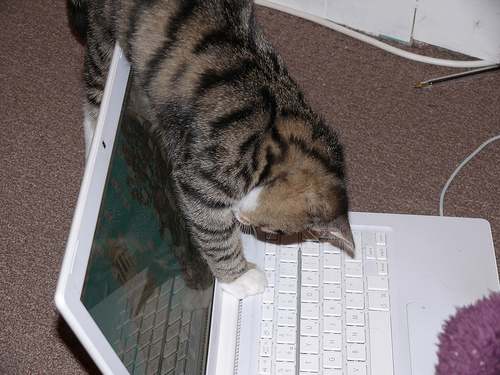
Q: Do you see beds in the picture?
A: No, there are no beds.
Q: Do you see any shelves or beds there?
A: No, there are no beds or shelves.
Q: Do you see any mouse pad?
A: No, there are no mouse pads.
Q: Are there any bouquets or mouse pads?
A: No, there are no mouse pads or bouquets.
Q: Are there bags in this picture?
A: No, there are no bags.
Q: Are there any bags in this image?
A: No, there are no bags.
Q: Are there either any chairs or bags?
A: No, there are no bags or chairs.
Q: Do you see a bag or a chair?
A: No, there are no bags or chairs.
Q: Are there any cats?
A: Yes, there is a cat.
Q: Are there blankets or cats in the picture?
A: Yes, there is a cat.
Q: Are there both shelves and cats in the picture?
A: No, there is a cat but no shelves.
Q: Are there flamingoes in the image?
A: No, there are no flamingoes.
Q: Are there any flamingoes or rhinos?
A: No, there are no flamingoes or rhinos.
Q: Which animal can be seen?
A: The animal is a cat.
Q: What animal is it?
A: The animal is a cat.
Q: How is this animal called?
A: This is a cat.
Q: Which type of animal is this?
A: This is a cat.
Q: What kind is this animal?
A: This is a cat.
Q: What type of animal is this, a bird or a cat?
A: This is a cat.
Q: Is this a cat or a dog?
A: This is a cat.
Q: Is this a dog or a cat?
A: This is a cat.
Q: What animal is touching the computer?
A: The cat is touching the computer.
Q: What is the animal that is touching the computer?
A: The animal is a cat.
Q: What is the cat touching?
A: The cat is touching the computer.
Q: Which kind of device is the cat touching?
A: The cat is touching the computer.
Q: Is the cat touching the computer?
A: Yes, the cat is touching the computer.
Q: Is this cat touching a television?
A: No, the cat is touching the computer.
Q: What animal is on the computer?
A: The cat is on the computer.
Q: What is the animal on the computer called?
A: The animal is a cat.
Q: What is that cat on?
A: The cat is on the computer.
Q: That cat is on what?
A: The cat is on the computer.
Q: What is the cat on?
A: The cat is on the computer.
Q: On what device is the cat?
A: The cat is on the computer.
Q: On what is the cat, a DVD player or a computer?
A: The cat is on a computer.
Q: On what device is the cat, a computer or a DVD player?
A: The cat is on a computer.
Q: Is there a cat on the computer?
A: Yes, there is a cat on the computer.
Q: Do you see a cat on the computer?
A: Yes, there is a cat on the computer.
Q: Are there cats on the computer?
A: Yes, there is a cat on the computer.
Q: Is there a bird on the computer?
A: No, there is a cat on the computer.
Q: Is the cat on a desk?
A: No, the cat is on the computer.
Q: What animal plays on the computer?
A: The cat plays on the computer.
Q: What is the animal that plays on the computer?
A: The animal is a cat.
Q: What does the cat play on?
A: The cat plays on the computer.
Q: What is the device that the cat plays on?
A: The device is a computer.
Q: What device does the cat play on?
A: The cat plays on the computer.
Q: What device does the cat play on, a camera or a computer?
A: The cat plays on a computer.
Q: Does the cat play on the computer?
A: Yes, the cat plays on the computer.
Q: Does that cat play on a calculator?
A: No, the cat plays on the computer.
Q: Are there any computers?
A: Yes, there is a computer.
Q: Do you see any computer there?
A: Yes, there is a computer.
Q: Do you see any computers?
A: Yes, there is a computer.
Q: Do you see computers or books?
A: Yes, there is a computer.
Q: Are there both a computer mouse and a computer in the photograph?
A: No, there is a computer but no computer mice.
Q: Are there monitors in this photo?
A: No, there are no monitors.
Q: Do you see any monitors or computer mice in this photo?
A: No, there are no monitors or computer mice.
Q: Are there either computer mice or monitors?
A: No, there are no monitors or computer mice.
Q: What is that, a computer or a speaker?
A: That is a computer.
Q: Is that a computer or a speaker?
A: That is a computer.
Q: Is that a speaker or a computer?
A: That is a computer.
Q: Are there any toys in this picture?
A: Yes, there is a toy.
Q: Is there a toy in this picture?
A: Yes, there is a toy.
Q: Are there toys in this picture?
A: Yes, there is a toy.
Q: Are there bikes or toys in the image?
A: Yes, there is a toy.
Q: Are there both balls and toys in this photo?
A: No, there is a toy but no balls.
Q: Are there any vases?
A: No, there are no vases.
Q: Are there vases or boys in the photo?
A: No, there are no vases or boys.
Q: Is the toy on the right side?
A: Yes, the toy is on the right of the image.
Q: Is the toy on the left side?
A: No, the toy is on the right of the image.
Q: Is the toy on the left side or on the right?
A: The toy is on the right of the image.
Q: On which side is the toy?
A: The toy is on the right of the image.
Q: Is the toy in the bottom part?
A: Yes, the toy is in the bottom of the image.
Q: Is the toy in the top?
A: No, the toy is in the bottom of the image.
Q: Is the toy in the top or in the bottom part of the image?
A: The toy is in the bottom of the image.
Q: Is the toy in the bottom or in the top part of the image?
A: The toy is in the bottom of the image.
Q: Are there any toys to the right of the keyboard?
A: Yes, there is a toy to the right of the keyboard.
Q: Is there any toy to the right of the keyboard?
A: Yes, there is a toy to the right of the keyboard.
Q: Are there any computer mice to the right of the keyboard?
A: No, there is a toy to the right of the keyboard.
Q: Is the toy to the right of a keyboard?
A: Yes, the toy is to the right of a keyboard.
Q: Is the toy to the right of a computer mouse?
A: No, the toy is to the right of a keyboard.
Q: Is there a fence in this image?
A: No, there are no fences.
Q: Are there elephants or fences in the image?
A: No, there are no fences or elephants.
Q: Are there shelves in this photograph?
A: No, there are no shelves.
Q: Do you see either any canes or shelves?
A: No, there are no shelves or canes.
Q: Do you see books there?
A: No, there are no books.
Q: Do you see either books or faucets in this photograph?
A: No, there are no books or faucets.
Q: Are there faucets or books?
A: No, there are no books or faucets.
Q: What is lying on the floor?
A: The pen is lying on the floor.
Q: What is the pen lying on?
A: The pen is lying on the floor.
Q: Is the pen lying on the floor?
A: Yes, the pen is lying on the floor.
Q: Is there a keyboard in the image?
A: Yes, there is a keyboard.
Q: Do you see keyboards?
A: Yes, there is a keyboard.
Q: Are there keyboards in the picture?
A: Yes, there is a keyboard.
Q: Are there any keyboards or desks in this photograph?
A: Yes, there is a keyboard.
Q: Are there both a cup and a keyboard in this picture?
A: No, there is a keyboard but no cups.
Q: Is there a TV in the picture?
A: No, there are no televisions.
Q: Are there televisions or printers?
A: No, there are no televisions or printers.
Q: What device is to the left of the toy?
A: The device is a keyboard.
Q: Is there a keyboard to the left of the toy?
A: Yes, there is a keyboard to the left of the toy.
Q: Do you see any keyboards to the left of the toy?
A: Yes, there is a keyboard to the left of the toy.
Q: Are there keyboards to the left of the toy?
A: Yes, there is a keyboard to the left of the toy.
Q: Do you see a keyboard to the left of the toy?
A: Yes, there is a keyboard to the left of the toy.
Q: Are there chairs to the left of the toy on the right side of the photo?
A: No, there is a keyboard to the left of the toy.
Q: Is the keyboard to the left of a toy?
A: Yes, the keyboard is to the left of a toy.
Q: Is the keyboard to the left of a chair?
A: No, the keyboard is to the left of a toy.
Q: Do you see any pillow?
A: No, there are no pillows.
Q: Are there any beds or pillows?
A: No, there are no pillows or beds.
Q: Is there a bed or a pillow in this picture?
A: No, there are no pillows or beds.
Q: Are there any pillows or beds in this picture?
A: No, there are no pillows or beds.